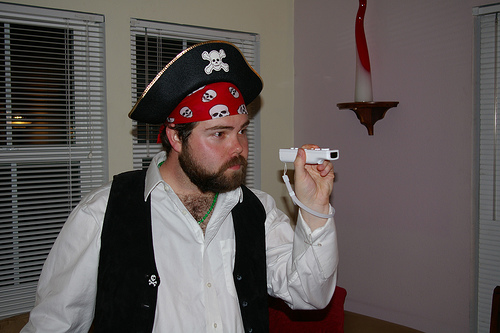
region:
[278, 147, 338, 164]
the wii controller in the man's hand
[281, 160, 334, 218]
the strap for the wii controller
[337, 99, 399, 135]
the shelf on the wall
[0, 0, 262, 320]
the horizontal blinds on the window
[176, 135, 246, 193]
the hair on the man's face and neck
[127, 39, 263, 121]
the hat on the man's head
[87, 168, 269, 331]
the vest on the man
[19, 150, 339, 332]
the white shirt on the man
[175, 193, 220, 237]
the hair on the man's chest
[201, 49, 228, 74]
the skull and bones on the man's hat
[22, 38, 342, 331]
Man wearing a pirate costume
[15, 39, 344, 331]
Man holding a Wii controller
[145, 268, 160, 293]
Skull and crossbones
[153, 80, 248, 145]
Red bandana with white skulls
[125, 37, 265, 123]
Black pirate hat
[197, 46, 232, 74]
Skull and crossbones on a pirate hat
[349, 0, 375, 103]
Red and white glass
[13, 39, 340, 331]
Man playing video games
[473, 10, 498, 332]
Closed white blinds on a window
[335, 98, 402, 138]
Dark brown wall mount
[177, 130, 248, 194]
Young man's full beard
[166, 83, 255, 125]
Young man wearing a pirate bandana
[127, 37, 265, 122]
Man wearing a black pirate hat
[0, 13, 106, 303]
White blinds on window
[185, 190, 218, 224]
Man wearing green necklace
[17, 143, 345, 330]
Man wearing a white dress shirt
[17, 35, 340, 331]
Young man wearing a pirate costume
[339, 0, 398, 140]
Glass decorative funnel-like accessory on wooden wall shelf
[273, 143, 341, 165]
a man with a wiimote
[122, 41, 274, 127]
a man with a pirate hat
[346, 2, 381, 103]
a red and white ornament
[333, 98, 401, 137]
a wooden ledge for the wall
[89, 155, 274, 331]
a man with a pirate vest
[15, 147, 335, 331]
a man with a white shirt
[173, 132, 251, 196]
a man with a beard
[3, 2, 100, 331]
a window in the background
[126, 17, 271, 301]
a window in the background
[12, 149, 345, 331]
Man wearing a shirt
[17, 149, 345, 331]
Man is wearing a shirt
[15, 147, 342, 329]
Man wearing a white shirt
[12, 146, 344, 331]
Man is wearing a white shirt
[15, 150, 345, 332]
Man wearing a dress shirt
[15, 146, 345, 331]
Man is wearing a dress shirt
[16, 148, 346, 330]
Man wearing a white dress shirt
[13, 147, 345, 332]
Man is wearing a white dress shirt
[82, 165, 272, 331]
Man wearing a black vest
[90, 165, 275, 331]
Man is wearing a black vest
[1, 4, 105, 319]
long white window blinds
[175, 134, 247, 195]
a man's beard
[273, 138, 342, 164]
a white game controller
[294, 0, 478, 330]
a purple painted wall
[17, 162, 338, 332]
a man's long sleeve white shirt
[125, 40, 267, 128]
a black, gold and white pirate hat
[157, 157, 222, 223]
a green necklace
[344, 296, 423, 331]
a section of indoor carpet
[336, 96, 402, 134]
a small wall hanging shelf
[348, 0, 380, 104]
a tall red and white statue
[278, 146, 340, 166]
A Wii gaming console remote controller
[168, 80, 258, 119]
A red bandanna with skulls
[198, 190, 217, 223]
A green beaded necklace